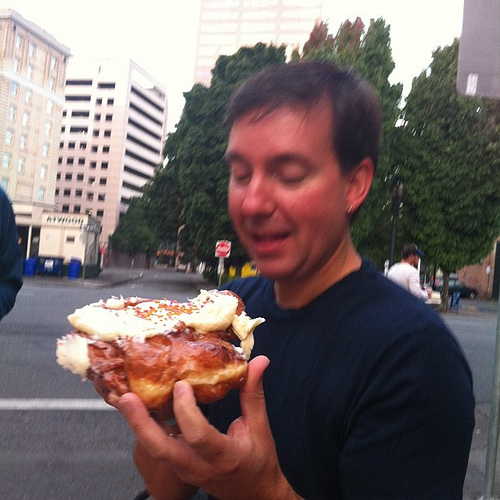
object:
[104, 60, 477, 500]
man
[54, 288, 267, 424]
food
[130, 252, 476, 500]
shirt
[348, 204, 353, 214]
earring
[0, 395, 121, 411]
traffic line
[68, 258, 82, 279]
trash bin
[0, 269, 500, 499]
street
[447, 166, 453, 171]
leaves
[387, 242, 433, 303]
man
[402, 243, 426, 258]
cap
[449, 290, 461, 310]
mailbox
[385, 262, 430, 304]
shirt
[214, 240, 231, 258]
stop sign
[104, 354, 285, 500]
hand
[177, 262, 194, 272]
car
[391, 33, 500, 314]
trees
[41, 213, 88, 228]
sign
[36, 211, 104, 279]
building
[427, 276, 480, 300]
car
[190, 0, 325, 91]
building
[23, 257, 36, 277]
trash bin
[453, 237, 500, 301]
building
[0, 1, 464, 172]
sky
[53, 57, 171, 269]
building